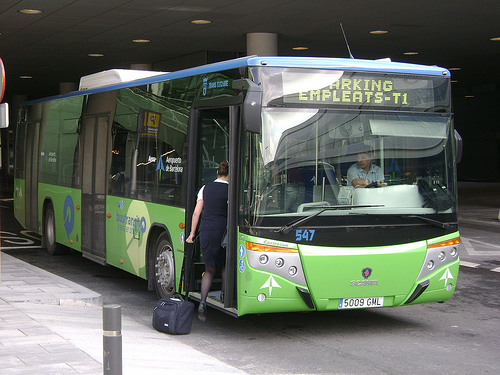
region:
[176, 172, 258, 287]
the dress is blue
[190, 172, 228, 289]
the dress is blue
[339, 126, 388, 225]
a man behind the wheel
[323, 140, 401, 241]
a man behind the wheel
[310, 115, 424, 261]
a man behind the wheel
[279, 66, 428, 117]
Sign on front of bus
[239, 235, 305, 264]
Right turn signal of bus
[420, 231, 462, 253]
Left turn signal of bus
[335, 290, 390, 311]
White and black license plate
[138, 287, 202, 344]
Dark luggage on street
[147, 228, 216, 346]
Woman pulling bag on bus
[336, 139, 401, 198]
Man sitting on green bus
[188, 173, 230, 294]
Woman wearing a blue dress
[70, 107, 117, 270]
Doors in center of bus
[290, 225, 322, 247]
Number 547 on bus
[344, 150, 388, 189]
The bus driver sitting at the wheel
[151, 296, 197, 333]
A bag of luggage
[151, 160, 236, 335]
A woman boarding the bus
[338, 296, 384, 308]
The front license plate on a bus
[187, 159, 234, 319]
A woman wearing a black dress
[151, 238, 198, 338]
A black bag with a long handle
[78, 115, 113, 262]
The middle doors on a bus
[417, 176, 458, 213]
A black back pack by the window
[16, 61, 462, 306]
A large green city bus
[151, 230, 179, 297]
The front wheel of a bus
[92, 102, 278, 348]
woman is get on the bus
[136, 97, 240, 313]
woman is get on the bus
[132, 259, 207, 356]
the bag is black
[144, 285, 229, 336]
the bag is black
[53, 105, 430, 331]
green and black bus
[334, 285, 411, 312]
black and white license plate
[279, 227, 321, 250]
blue number on bus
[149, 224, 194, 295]
bus has black wheels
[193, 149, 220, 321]
woman stepping on bus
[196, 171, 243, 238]
woman has blue vest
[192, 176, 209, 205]
woman has white shirt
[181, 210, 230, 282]
woman has blue pants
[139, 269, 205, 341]
woman has blue bag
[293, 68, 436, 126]
green LCD screen on bus